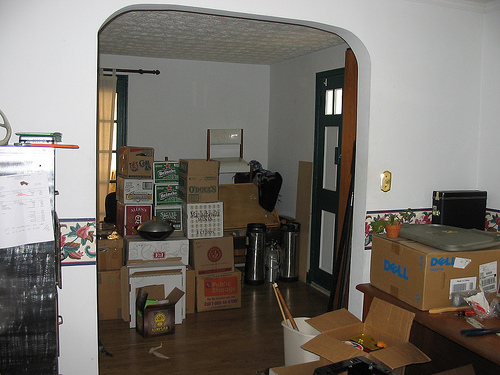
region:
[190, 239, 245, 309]
boxes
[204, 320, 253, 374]
the wooden floor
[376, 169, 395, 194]
light switch on the wall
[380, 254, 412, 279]
logo on the box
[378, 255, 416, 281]
the logo is blue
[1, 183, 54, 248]
a paper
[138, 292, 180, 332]
a box on the floor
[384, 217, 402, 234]
a small plant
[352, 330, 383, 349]
items in the box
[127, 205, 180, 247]
black and silver pot on a box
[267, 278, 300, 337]
pool cue in a white trash can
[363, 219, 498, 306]
cardboard dell box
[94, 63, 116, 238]
off white colored curtain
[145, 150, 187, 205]
heineken beer boxes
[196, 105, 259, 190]
white chair on top of some boxes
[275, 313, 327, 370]
white plastic trash can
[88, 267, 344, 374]
wooden floor in a house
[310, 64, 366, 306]
green and white door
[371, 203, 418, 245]
plant on a dell box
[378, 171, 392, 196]
light switch sits on wall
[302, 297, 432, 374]
box is open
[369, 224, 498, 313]
box is closed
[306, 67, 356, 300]
door is closed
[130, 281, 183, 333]
box is open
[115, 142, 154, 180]
box is closed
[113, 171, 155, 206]
box is closed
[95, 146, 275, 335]
boxes are stacked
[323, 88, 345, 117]
the sun is shining through the glass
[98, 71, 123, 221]
curtain hangs on window in the background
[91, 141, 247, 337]
Boxes stacked on the floor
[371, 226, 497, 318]
Dell box on the table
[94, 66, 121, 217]
Curtain covering the window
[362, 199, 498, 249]
Border on the wall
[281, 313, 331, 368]
White garbage pail on the floor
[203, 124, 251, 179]
Chair on top of the boxes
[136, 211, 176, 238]
Pan on top of the boes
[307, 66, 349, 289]
Brown and white door with windows on top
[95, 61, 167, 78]
Curtain rod over the window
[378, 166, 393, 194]
Light switch with decorative cover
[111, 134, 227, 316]
a stack of cardboard boxes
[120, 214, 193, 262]
a wok with a lid on it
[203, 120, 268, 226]
two chairs stacked against a wall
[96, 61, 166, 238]
a yellow curtain on a window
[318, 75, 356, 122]
glass windows in a door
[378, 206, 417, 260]
a small potted plant on a box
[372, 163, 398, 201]
a metal switchplate with yellow trim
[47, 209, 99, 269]
a pink and green pattern wallpaper border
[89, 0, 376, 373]
an arched doorway to the next room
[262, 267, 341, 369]
a white trash can with trash in it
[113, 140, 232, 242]
Boxes stacked on each other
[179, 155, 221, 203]
Cardboard brown box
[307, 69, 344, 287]
a green and white door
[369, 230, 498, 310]
a box with DELL on it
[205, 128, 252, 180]
a white chair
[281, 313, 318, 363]
a cream colored bin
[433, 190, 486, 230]
a black chest in the corner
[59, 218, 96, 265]
floral design on the wall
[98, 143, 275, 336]
boxes gathered in a room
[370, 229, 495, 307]
a box on the table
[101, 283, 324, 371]
hard wooden floor